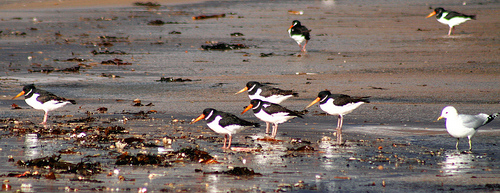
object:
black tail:
[356, 94, 372, 104]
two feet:
[451, 147, 477, 156]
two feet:
[329, 126, 344, 134]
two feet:
[268, 133, 279, 139]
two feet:
[219, 145, 233, 150]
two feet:
[36, 121, 49, 126]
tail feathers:
[484, 110, 498, 120]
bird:
[10, 80, 79, 126]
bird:
[286, 19, 314, 57]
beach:
[2, 0, 498, 164]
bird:
[237, 98, 309, 138]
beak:
[240, 104, 254, 115]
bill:
[302, 88, 339, 113]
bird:
[232, 80, 301, 108]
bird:
[302, 90, 376, 131]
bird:
[187, 107, 263, 147]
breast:
[204, 114, 226, 135]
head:
[191, 107, 217, 124]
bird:
[424, 6, 477, 36]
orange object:
[376, 145, 386, 150]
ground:
[1, 0, 493, 188]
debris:
[0, 113, 270, 188]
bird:
[431, 104, 495, 153]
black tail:
[485, 110, 498, 122]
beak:
[435, 113, 444, 123]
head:
[436, 105, 460, 121]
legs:
[337, 113, 344, 128]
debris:
[63, 40, 206, 87]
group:
[181, 74, 383, 149]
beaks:
[188, 113, 205, 124]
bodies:
[251, 101, 304, 125]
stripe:
[319, 94, 330, 103]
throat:
[318, 94, 332, 104]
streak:
[200, 109, 226, 126]